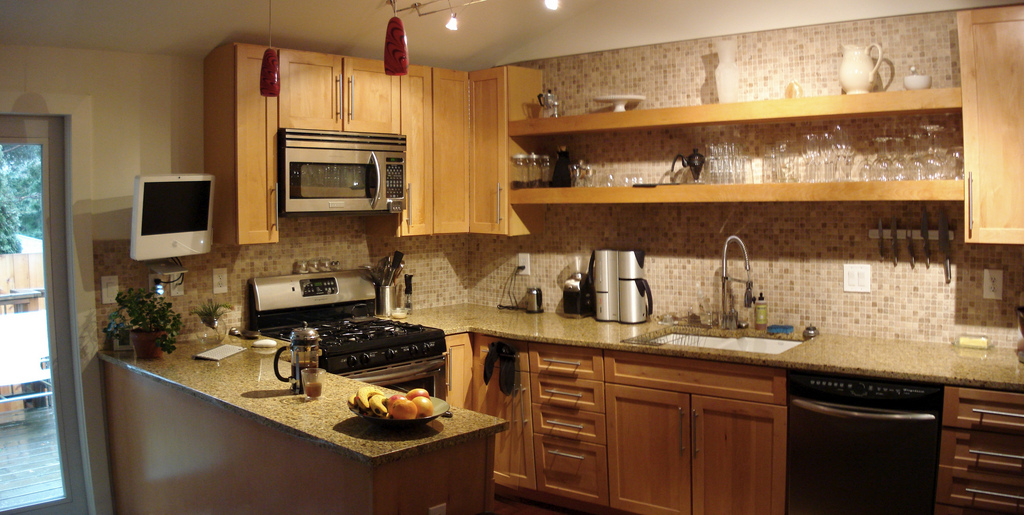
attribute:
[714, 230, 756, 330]
faucet — large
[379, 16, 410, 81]
lamp shade — red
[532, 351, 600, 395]
drawer —  closed,  kitchen's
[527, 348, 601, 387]
drawer —  kitchen's,  closed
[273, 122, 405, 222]
microwave — built in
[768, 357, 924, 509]
dishwasher — built in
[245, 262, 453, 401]
stove — silver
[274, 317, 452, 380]
burners — black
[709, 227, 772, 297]
faucet — silver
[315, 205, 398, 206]
microwave oven — black and stainless steel 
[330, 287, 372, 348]
stovetop — black and stainless steel 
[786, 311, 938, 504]
dishwasher — black 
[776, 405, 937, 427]
handle — silver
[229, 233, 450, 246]
drawers — wooden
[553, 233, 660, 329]
coffee maker — black, white